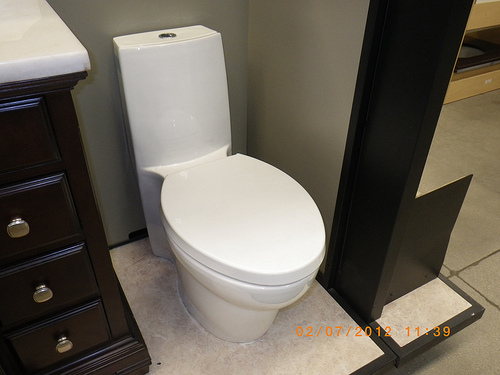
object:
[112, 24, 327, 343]
toilet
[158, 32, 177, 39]
valve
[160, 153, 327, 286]
lid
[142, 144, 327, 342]
base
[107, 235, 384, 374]
floor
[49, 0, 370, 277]
wall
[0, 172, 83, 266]
drawer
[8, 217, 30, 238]
handle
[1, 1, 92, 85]
counter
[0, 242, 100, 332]
drawer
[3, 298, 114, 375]
drawer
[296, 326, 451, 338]
date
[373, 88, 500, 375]
floor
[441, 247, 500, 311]
crack